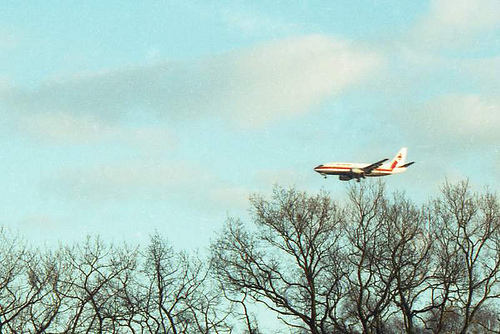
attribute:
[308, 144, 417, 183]
airplane — white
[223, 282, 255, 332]
branch — skinny, tree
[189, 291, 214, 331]
branch — skinny, tree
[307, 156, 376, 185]
line — red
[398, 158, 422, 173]
wing — side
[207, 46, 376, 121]
clouds — white